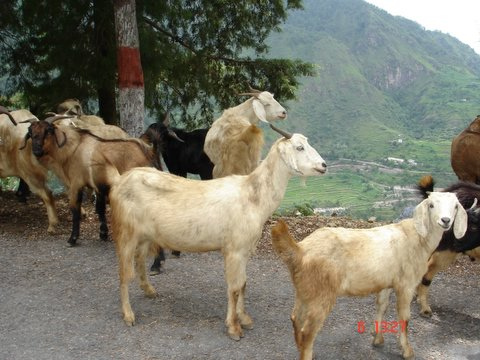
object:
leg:
[111, 227, 138, 313]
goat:
[80, 123, 328, 343]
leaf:
[215, 21, 228, 33]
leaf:
[184, 56, 195, 63]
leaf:
[273, 66, 285, 79]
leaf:
[249, 63, 265, 75]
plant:
[0, 0, 323, 179]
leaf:
[144, 75, 159, 88]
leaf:
[50, 50, 64, 60]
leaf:
[155, 97, 167, 109]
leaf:
[70, 54, 83, 62]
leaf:
[164, 55, 178, 63]